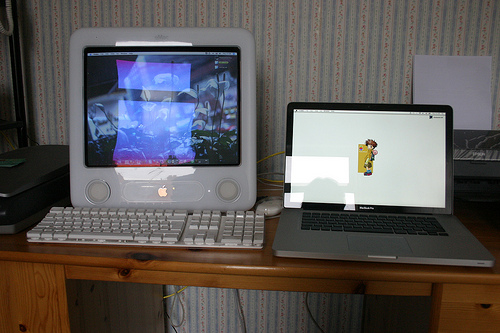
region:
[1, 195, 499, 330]
brown wooden computer desk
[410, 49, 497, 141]
paper in a priner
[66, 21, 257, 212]
white apple computer monitor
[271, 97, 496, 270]
laptop computer on a desk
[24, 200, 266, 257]
white keyboard on the desk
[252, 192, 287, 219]
white computer mouse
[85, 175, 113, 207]
left dial on monitor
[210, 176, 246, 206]
right dial on monitor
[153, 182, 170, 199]
apple logo on monitor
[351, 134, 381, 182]
cartoon image on monitor on right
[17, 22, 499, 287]
two computers on a wooden desk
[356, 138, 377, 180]
anime character on a laptop screen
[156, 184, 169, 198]
bitten apple logo on an apple computer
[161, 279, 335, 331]
power cords hanging behind the desk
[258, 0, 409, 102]
blue striped floral wallpaper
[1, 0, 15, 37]
white spiral telephone cord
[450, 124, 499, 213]
gray printer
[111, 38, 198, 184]
sunlight creating glare on a computer monitor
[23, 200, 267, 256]
white keyboard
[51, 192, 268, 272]
Computer has white keyboard.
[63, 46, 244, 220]
Apple monitor is white.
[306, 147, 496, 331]
Laptop is black and silver.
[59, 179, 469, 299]
Computers are sitting on brown desk.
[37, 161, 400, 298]
Brown desk is wooden.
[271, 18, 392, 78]
Red, white, and blue wall paper on wall.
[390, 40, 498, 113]
White paper sticking out of printer.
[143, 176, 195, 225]
Apple logo on monitor.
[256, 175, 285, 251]
White computer mouse near monitor.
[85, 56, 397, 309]
2 computers next to each other.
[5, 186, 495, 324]
a brown wood desk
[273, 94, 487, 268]
a laptop on a desk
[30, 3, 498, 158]
blue striped wallpaper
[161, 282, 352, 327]
cords running under a desk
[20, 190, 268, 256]
a grey keyboard in front of a monitor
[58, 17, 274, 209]
a monitor behind a keyboard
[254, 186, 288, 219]
a mouse on a desk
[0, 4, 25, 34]
a telephone cord hanging down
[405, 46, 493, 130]
paper in a printer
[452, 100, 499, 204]
a printer holding paper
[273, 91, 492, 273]
Laptop computer sitting on desk.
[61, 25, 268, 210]
Computer monitor sitting on desk.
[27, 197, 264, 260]
Computer keyboard sitting on desk.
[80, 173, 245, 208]
Control knobs for monitor.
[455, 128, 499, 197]
Printer sitting in background on desk.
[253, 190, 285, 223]
Computer mouse lying on desk.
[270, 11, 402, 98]
Printed wallpaper on wall of room.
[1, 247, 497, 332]
A brown wood computer desk.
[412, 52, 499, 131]
Paper rising from printer.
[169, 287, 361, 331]
Power cords hanging from computers.